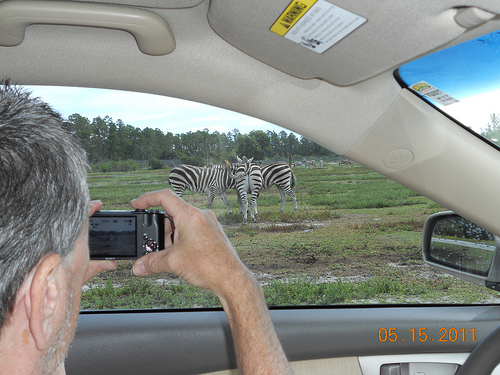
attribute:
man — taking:
[36, 87, 207, 145]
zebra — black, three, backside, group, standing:
[192, 163, 255, 220]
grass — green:
[351, 194, 391, 222]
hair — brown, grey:
[21, 153, 66, 215]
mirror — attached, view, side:
[403, 199, 490, 295]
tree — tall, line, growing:
[151, 128, 191, 160]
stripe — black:
[228, 171, 262, 207]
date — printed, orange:
[366, 314, 492, 370]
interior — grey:
[338, 318, 422, 367]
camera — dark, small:
[78, 191, 179, 267]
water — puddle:
[304, 267, 354, 298]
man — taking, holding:
[21, 79, 197, 371]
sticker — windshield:
[397, 60, 476, 136]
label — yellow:
[251, 7, 304, 64]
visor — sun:
[195, 9, 453, 119]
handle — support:
[12, 8, 157, 83]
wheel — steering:
[474, 336, 487, 364]